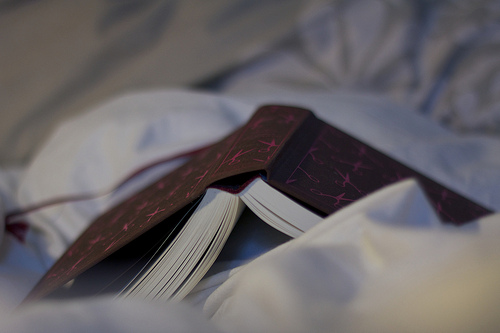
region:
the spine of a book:
[198, 95, 312, 190]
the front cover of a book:
[11, 125, 223, 315]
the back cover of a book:
[263, 101, 499, 263]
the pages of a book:
[100, 175, 329, 304]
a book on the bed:
[6, 100, 493, 315]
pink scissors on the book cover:
[307, 182, 364, 212]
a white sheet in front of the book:
[0, 170, 494, 327]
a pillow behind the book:
[0, 65, 264, 252]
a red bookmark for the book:
[2, 138, 219, 244]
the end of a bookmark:
[1, 209, 43, 246]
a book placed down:
[33, 97, 378, 303]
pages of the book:
[167, 194, 256, 268]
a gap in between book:
[206, 187, 295, 269]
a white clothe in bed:
[42, 63, 412, 171]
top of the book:
[49, 172, 202, 302]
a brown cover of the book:
[56, 151, 208, 267]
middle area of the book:
[223, 98, 285, 240]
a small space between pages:
[181, 245, 218, 290]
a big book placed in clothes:
[76, 37, 474, 284]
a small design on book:
[44, 156, 236, 251]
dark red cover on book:
[60, 116, 386, 273]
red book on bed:
[51, 127, 422, 300]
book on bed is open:
[42, 124, 465, 320]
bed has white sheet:
[94, 67, 373, 316]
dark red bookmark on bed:
[61, 96, 228, 183]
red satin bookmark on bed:
[3, 129, 211, 254]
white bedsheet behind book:
[35, 68, 190, 215]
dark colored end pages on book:
[67, 191, 213, 331]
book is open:
[101, 156, 270, 325]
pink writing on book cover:
[57, 114, 202, 276]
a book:
[60, 110, 290, 325]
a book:
[128, 5, 360, 310]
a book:
[191, 127, 282, 271]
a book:
[194, 60, 306, 330]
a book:
[142, 102, 293, 279]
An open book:
[30, 98, 470, 308]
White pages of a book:
[120, 193, 242, 302]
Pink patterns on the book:
[310, 131, 372, 204]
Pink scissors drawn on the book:
[225, 135, 292, 171]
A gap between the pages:
[214, 210, 289, 282]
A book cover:
[40, 206, 165, 276]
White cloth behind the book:
[40, 72, 212, 162]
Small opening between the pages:
[182, 222, 209, 289]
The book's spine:
[226, 90, 302, 192]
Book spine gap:
[203, 170, 270, 192]